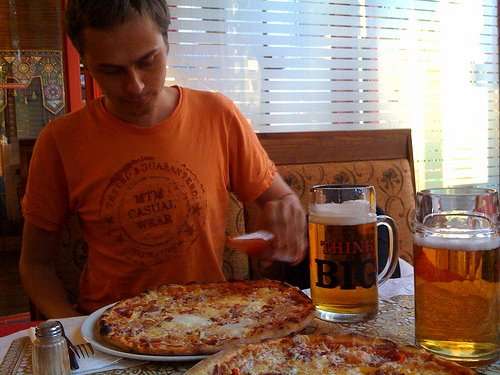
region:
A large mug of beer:
[307, 182, 399, 324]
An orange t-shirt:
[18, 83, 279, 318]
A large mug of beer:
[410, 187, 499, 364]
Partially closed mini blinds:
[163, 0, 498, 199]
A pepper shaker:
[28, 319, 73, 374]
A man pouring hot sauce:
[16, 0, 309, 325]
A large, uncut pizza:
[95, 277, 317, 356]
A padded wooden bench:
[30, 125, 421, 325]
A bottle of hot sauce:
[223, 227, 306, 268]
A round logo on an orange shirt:
[97, 152, 210, 270]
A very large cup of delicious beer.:
[305, 180, 400, 325]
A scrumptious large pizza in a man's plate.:
[90, 275, 315, 355]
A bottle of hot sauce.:
[220, 220, 300, 265]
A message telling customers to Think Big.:
[310, 235, 375, 290]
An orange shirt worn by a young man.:
[15, 80, 275, 310]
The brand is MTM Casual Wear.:
[120, 180, 176, 230]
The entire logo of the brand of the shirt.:
[92, 150, 207, 266]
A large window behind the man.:
[160, 0, 495, 190]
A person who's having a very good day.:
[15, 0, 305, 320]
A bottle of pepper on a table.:
[30, 316, 70, 371]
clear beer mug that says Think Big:
[308, 181, 398, 325]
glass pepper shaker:
[29, 317, 69, 372]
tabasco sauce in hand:
[226, 227, 305, 266]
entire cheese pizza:
[86, 277, 313, 356]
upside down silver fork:
[54, 319, 94, 357]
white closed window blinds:
[158, 2, 378, 132]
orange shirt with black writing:
[24, 91, 271, 292]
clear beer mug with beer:
[413, 190, 498, 362]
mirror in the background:
[12, 46, 64, 137]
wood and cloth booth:
[38, 126, 419, 271]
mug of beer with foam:
[301, 180, 401, 329]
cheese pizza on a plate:
[103, 276, 313, 345]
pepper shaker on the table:
[28, 322, 83, 369]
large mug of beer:
[406, 172, 498, 362]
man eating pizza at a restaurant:
[18, 9, 284, 336]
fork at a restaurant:
[53, 315, 101, 364]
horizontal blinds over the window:
[290, 29, 483, 88]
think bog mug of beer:
[314, 234, 386, 301]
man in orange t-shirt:
[14, 90, 284, 276]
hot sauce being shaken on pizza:
[218, 214, 319, 279]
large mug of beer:
[297, 177, 408, 332]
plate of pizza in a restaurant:
[90, 271, 321, 359]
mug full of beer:
[404, 181, 498, 355]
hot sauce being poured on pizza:
[224, 218, 311, 273]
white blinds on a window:
[238, 21, 420, 99]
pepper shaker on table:
[25, 317, 67, 374]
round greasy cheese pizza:
[98, 280, 308, 355]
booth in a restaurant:
[284, 107, 424, 218]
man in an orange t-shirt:
[31, 18, 238, 295]